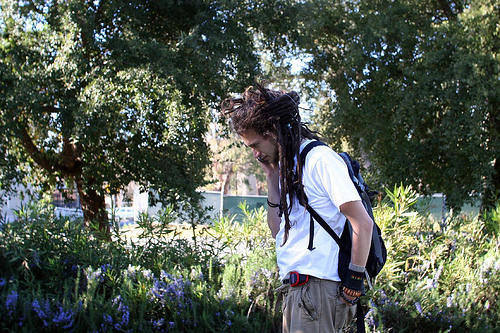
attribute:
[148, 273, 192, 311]
flowers — blue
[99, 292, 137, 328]
flowers — blue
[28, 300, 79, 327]
flowers — blue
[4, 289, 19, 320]
flowers — blue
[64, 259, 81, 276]
flowers — blue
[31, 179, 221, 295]
hedge — overgrown 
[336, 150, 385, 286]
backpack — black , gray  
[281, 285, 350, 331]
shorts — cargo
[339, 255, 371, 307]
glove — dark colored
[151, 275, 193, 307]
flowers — blue/purple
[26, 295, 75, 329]
flowers — blue/purple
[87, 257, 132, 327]
flowers — blue/purple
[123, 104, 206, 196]
leaves — dark, green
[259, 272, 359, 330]
pants — grey 